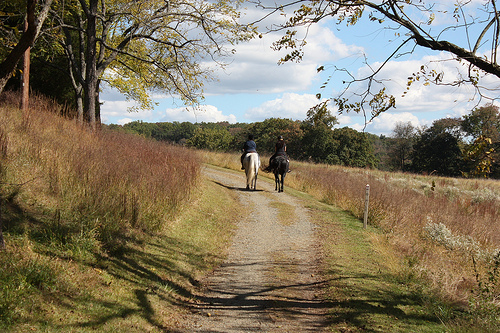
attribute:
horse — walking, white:
[240, 150, 263, 191]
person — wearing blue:
[240, 133, 262, 162]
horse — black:
[266, 152, 293, 190]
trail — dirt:
[229, 196, 320, 333]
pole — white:
[362, 181, 379, 240]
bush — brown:
[121, 150, 200, 217]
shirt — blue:
[244, 138, 260, 152]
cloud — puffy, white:
[303, 27, 356, 68]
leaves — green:
[116, 56, 157, 102]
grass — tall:
[24, 223, 157, 273]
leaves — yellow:
[480, 136, 498, 165]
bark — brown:
[19, 47, 33, 110]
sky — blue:
[349, 24, 379, 47]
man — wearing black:
[273, 136, 291, 152]